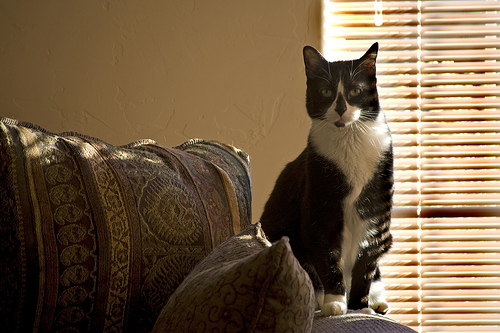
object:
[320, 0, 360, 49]
sunlight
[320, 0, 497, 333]
miniblinds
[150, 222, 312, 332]
pillow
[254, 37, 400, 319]
cat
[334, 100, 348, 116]
nose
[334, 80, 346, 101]
spot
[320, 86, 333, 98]
eye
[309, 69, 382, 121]
face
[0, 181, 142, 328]
couch fabric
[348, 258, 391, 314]
arm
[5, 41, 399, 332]
cat all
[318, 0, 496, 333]
window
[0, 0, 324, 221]
wall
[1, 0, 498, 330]
house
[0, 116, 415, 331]
couch